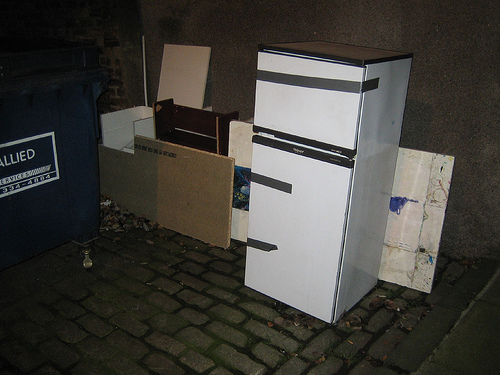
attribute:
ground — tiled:
[0, 257, 471, 374]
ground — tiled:
[0, 211, 461, 372]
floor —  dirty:
[1, 213, 499, 373]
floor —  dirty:
[0, 190, 500, 372]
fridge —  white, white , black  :
[240, 35, 417, 325]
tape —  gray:
[254, 66, 381, 96]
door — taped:
[244, 42, 364, 325]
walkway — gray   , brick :
[13, 253, 342, 371]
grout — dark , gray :
[252, 335, 262, 340]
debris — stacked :
[97, 39, 458, 324]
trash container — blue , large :
[1, 40, 104, 269]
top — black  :
[261, 35, 417, 65]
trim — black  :
[257, 37, 413, 64]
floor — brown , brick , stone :
[1, 259, 495, 373]